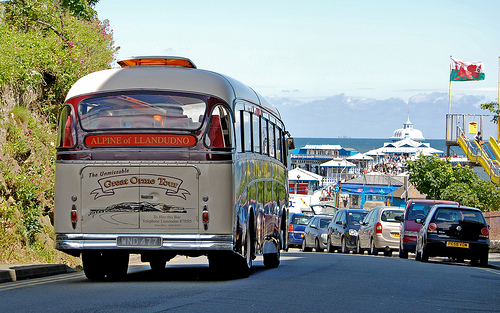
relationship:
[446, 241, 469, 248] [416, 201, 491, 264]
license plate on car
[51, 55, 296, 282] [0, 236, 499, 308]
bus on road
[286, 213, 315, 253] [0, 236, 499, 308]
car alongside road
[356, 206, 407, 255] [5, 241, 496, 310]
car alongside road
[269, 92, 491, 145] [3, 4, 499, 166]
mountain in distance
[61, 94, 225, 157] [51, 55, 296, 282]
window of bus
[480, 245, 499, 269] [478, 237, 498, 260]
part of sidewalk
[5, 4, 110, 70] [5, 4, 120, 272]
trees of trees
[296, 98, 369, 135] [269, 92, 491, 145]
part of mountain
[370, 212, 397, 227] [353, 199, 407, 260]
part of car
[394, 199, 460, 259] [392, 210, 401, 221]
truck has side mirror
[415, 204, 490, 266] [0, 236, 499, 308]
car on road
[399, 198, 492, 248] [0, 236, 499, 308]
car on road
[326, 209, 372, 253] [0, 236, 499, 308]
car on road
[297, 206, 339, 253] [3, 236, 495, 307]
car on street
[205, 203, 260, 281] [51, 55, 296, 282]
tire on bus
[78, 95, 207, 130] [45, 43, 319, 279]
window on bus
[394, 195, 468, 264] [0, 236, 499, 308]
truck parked on road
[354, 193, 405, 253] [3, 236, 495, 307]
car parked on street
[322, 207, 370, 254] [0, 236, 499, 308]
car parked on road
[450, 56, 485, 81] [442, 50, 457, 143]
flag on pole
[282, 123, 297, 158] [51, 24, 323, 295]
mirror on bus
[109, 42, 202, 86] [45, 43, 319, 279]
vent on top of bus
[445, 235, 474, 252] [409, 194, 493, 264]
license plate on car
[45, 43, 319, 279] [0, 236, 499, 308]
bus on road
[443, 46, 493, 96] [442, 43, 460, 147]
flag on pole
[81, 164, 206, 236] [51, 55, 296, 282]
advertisement painted on bus